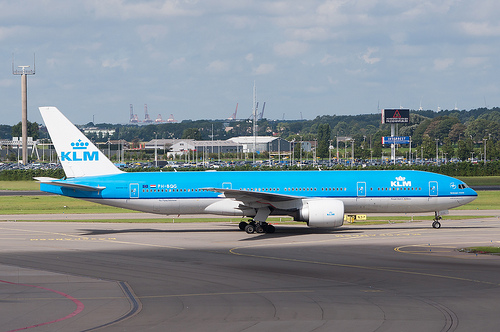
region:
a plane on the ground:
[22, 36, 464, 295]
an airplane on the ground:
[14, 38, 493, 309]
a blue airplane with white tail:
[14, 55, 427, 329]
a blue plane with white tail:
[47, 48, 497, 325]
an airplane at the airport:
[4, 34, 498, 301]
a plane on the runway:
[15, 66, 497, 258]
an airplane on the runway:
[34, 33, 499, 330]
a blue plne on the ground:
[29, 65, 499, 222]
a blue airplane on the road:
[42, 58, 497, 274]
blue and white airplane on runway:
[37, 112, 491, 250]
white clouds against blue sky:
[20, 16, 98, 63]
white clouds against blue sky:
[25, 59, 99, 103]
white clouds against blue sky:
[100, 71, 171, 119]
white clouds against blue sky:
[131, 21, 199, 63]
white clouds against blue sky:
[240, 28, 307, 65]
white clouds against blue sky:
[184, 55, 232, 86]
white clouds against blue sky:
[268, 52, 343, 107]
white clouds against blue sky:
[317, 8, 418, 88]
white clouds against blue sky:
[412, 12, 477, 89]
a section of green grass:
[464, 242, 497, 259]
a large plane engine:
[296, 197, 345, 229]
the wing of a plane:
[195, 181, 301, 215]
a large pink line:
[5, 276, 80, 330]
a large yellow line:
[226, 235, 498, 305]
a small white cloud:
[263, 41, 314, 58]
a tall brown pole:
[19, 68, 35, 163]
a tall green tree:
[463, 105, 498, 145]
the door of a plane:
[354, 176, 367, 201]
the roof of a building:
[227, 130, 275, 144]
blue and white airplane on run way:
[48, 100, 467, 244]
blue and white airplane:
[22, 94, 469, 261]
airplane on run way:
[24, 103, 468, 236]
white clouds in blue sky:
[9, 8, 97, 57]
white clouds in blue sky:
[59, 45, 146, 92]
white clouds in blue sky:
[147, 20, 229, 68]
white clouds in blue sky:
[234, 51, 337, 91]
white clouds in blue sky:
[284, 18, 357, 69]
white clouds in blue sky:
[398, 2, 475, 59]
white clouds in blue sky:
[292, 62, 413, 92]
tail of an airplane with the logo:
[25, 99, 131, 179]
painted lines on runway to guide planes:
[25, 218, 134, 263]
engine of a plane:
[297, 193, 352, 228]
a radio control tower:
[7, 53, 42, 170]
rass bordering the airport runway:
[7, 193, 45, 210]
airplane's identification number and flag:
[140, 174, 185, 193]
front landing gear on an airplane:
[431, 209, 446, 228]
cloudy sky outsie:
[167, 13, 424, 95]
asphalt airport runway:
[163, 243, 321, 313]